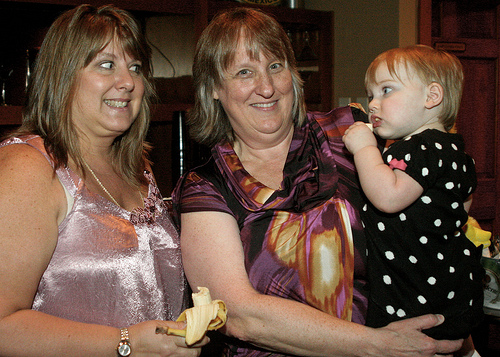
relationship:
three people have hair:
[65, 70, 392, 170] [29, 7, 466, 157]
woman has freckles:
[170, 7, 462, 357] [256, 299, 331, 353]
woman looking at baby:
[5, 10, 195, 305] [332, 40, 481, 350]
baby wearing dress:
[342, 44, 485, 340] [373, 128, 484, 316]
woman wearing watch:
[0, 4, 210, 357] [115, 326, 132, 354]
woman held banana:
[0, 4, 210, 357] [172, 274, 234, 354]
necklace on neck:
[74, 152, 146, 215] [63, 117, 117, 158]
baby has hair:
[342, 44, 485, 340] [365, 43, 466, 132]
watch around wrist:
[116, 322, 131, 355] [112, 317, 133, 355]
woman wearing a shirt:
[169, 6, 464, 355] [169, 102, 387, 355]